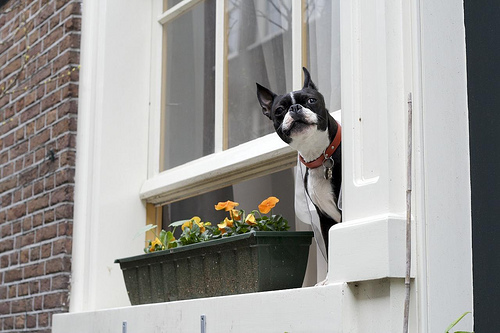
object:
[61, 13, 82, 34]
brick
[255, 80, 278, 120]
ear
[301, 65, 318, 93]
ear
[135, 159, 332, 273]
window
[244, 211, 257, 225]
flowers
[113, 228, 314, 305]
container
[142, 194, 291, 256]
flowers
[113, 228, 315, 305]
planter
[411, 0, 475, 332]
wall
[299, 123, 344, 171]
red collar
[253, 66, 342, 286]
boston terrier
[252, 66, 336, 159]
head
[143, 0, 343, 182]
window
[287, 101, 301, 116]
nose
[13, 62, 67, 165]
bricks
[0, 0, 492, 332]
building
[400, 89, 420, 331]
stick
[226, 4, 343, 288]
curtains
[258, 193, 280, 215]
flower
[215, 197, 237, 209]
flower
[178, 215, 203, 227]
flower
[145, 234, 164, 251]
flower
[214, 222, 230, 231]
flower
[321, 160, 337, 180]
metal tags